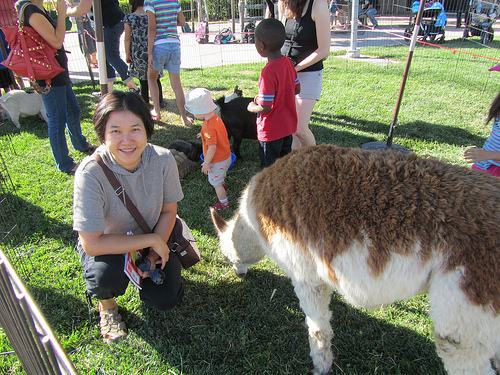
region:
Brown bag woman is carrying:
[87, 144, 207, 273]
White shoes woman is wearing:
[88, 302, 136, 354]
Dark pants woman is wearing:
[62, 223, 197, 316]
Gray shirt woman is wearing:
[65, 135, 190, 251]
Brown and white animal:
[203, 137, 498, 373]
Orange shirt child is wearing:
[190, 112, 237, 169]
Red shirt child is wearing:
[247, 53, 301, 144]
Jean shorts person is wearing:
[137, 39, 190, 80]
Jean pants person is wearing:
[24, 79, 91, 169]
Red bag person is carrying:
[1, 14, 69, 95]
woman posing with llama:
[57, 93, 497, 370]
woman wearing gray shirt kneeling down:
[62, 90, 208, 345]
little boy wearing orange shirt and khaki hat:
[180, 84, 246, 211]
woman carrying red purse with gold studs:
[2, 2, 94, 169]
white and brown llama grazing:
[201, 142, 499, 373]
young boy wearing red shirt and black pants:
[240, 19, 305, 169]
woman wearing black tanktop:
[272, 2, 344, 134]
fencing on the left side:
[2, 110, 85, 374]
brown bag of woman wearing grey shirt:
[86, 140, 201, 271]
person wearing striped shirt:
[136, 1, 203, 134]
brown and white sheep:
[230, 169, 469, 336]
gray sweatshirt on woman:
[71, 161, 191, 243]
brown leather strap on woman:
[99, 163, 187, 244]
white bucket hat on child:
[181, 81, 224, 118]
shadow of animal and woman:
[216, 263, 296, 373]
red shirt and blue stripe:
[239, 65, 326, 169]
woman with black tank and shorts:
[272, 0, 354, 111]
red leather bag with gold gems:
[3, 23, 88, 124]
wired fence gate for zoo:
[361, 13, 496, 114]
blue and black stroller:
[396, 0, 458, 37]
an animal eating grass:
[205, 161, 498, 373]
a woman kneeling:
[71, 88, 202, 348]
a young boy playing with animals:
[181, 89, 237, 211]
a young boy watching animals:
[241, 13, 298, 177]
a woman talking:
[13, 1, 83, 173]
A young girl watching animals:
[465, 53, 499, 175]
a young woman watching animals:
[141, 3, 192, 128]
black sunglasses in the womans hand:
[130, 253, 169, 290]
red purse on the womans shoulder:
[1, 18, 67, 90]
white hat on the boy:
[182, 83, 222, 117]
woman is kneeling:
[71, 87, 198, 342]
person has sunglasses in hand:
[136, 250, 171, 289]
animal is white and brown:
[208, 142, 498, 372]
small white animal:
[0, 81, 65, 131]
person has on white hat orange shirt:
[177, 89, 236, 212]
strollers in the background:
[406, 0, 498, 40]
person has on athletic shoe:
[90, 304, 131, 348]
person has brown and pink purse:
[90, 147, 201, 272]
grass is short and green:
[1, 34, 498, 373]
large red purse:
[3, 20, 61, 93]